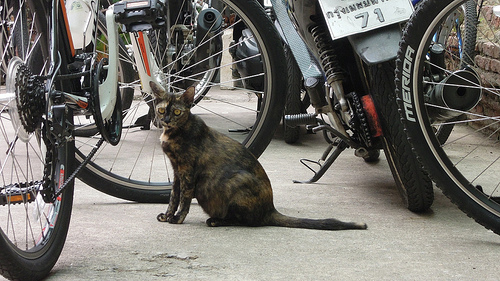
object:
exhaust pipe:
[416, 70, 484, 121]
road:
[1, 85, 499, 279]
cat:
[148, 81, 368, 231]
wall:
[443, 0, 499, 145]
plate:
[316, 0, 416, 41]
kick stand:
[292, 140, 349, 184]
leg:
[171, 180, 193, 224]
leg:
[155, 172, 180, 222]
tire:
[0, 0, 76, 280]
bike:
[394, 1, 497, 238]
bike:
[54, 0, 290, 203]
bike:
[0, 0, 76, 281]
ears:
[179, 86, 195, 104]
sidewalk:
[1, 80, 498, 281]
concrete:
[0, 83, 500, 278]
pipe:
[305, 23, 349, 112]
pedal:
[0, 181, 41, 206]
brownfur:
[204, 153, 257, 199]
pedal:
[110, 11, 166, 33]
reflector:
[136, 31, 150, 77]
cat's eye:
[172, 109, 181, 116]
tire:
[354, 30, 436, 213]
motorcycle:
[277, 0, 481, 210]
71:
[355, 8, 386, 28]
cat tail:
[270, 208, 369, 231]